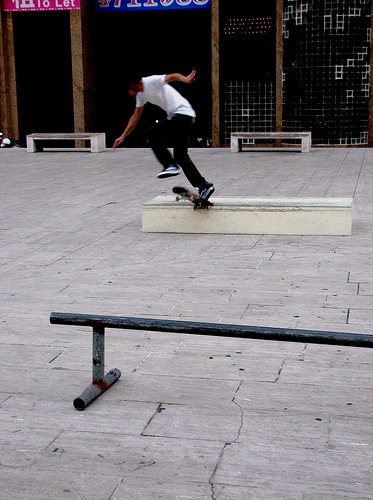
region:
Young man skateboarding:
[103, 52, 228, 213]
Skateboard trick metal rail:
[42, 304, 372, 418]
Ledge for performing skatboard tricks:
[136, 185, 359, 242]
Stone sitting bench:
[222, 122, 317, 156]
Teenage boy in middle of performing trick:
[100, 58, 230, 215]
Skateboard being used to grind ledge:
[168, 180, 215, 214]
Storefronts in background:
[0, 1, 371, 153]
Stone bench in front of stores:
[21, 124, 112, 156]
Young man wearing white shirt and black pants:
[102, 56, 227, 209]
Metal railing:
[39, 300, 371, 431]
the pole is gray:
[43, 308, 345, 357]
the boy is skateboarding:
[137, 150, 222, 218]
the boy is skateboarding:
[130, 122, 242, 242]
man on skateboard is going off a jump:
[109, 66, 214, 208]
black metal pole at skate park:
[47, 308, 367, 410]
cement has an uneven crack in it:
[206, 398, 243, 494]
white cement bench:
[227, 128, 311, 153]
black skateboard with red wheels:
[170, 184, 213, 209]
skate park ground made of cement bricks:
[1, 147, 368, 496]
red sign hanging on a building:
[0, 0, 82, 9]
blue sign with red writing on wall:
[95, 0, 211, 11]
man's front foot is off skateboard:
[155, 161, 212, 209]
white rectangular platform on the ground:
[140, 190, 356, 236]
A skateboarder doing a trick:
[113, 68, 215, 209]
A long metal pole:
[49, 308, 371, 411]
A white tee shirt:
[135, 73, 198, 122]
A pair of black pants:
[145, 114, 212, 184]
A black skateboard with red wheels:
[173, 186, 215, 211]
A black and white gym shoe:
[154, 164, 180, 176]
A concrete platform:
[140, 196, 353, 234]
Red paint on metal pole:
[91, 378, 109, 390]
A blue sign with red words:
[98, 0, 209, 9]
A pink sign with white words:
[0, 0, 79, 10]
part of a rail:
[292, 336, 299, 346]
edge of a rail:
[204, 324, 220, 353]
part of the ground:
[187, 412, 202, 444]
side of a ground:
[177, 430, 190, 444]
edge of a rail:
[105, 380, 109, 389]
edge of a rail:
[91, 382, 94, 387]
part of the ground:
[178, 389, 203, 427]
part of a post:
[164, 321, 169, 323]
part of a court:
[207, 421, 226, 448]